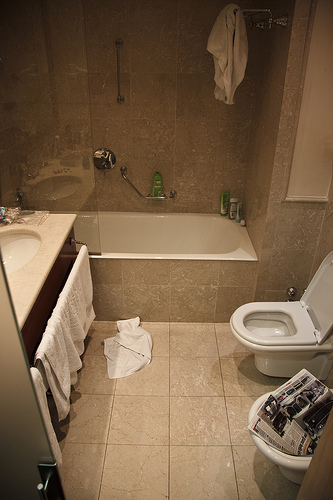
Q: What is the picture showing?
A: It is showing a bathroom.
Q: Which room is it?
A: It is a bathroom.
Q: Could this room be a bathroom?
A: Yes, it is a bathroom.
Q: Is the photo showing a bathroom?
A: Yes, it is showing a bathroom.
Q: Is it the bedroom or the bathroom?
A: It is the bathroom.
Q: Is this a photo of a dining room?
A: No, the picture is showing a bathroom.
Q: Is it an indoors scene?
A: Yes, it is indoors.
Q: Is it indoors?
A: Yes, it is indoors.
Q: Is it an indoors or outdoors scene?
A: It is indoors.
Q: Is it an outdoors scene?
A: No, it is indoors.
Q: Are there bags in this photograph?
A: Yes, there is a bag.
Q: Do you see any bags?
A: Yes, there is a bag.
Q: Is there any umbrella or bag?
A: Yes, there is a bag.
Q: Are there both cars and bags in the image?
A: No, there is a bag but no cars.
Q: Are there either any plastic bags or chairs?
A: Yes, there is a plastic bag.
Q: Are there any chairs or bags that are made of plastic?
A: Yes, the bag is made of plastic.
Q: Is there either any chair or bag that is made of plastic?
A: Yes, the bag is made of plastic.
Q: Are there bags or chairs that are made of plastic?
A: Yes, the bag is made of plastic.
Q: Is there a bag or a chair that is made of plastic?
A: Yes, the bag is made of plastic.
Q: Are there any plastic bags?
A: Yes, there is a bag that is made of plastic.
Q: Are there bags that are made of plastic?
A: Yes, there is a bag that is made of plastic.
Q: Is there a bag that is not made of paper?
A: Yes, there is a bag that is made of plastic.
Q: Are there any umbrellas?
A: No, there are no umbrellas.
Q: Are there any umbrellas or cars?
A: No, there are no umbrellas or cars.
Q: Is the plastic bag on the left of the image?
A: Yes, the bag is on the left of the image.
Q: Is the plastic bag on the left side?
A: Yes, the bag is on the left of the image.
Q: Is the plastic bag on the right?
A: No, the bag is on the left of the image.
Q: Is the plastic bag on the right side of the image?
A: No, the bag is on the left of the image.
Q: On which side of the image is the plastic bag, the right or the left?
A: The bag is on the left of the image.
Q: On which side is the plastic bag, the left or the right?
A: The bag is on the left of the image.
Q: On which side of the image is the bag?
A: The bag is on the left of the image.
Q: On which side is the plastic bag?
A: The bag is on the left of the image.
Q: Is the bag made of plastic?
A: Yes, the bag is made of plastic.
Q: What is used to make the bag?
A: The bag is made of plastic.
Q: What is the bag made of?
A: The bag is made of plastic.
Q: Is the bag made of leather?
A: No, the bag is made of plastic.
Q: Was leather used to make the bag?
A: No, the bag is made of plastic.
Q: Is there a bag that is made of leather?
A: No, there is a bag but it is made of plastic.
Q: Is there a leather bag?
A: No, there is a bag but it is made of plastic.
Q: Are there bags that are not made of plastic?
A: No, there is a bag but it is made of plastic.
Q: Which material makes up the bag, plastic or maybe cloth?
A: The bag is made of plastic.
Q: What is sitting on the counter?
A: The bag is sitting on the counter.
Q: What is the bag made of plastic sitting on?
A: The bag is sitting on the counter.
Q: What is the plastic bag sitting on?
A: The bag is sitting on the counter.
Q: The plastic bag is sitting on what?
A: The bag is sitting on the counter.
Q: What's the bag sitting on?
A: The bag is sitting on the counter.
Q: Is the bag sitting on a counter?
A: Yes, the bag is sitting on a counter.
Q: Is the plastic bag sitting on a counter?
A: Yes, the bag is sitting on a counter.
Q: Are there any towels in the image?
A: Yes, there is a towel.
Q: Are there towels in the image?
A: Yes, there is a towel.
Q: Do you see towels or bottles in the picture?
A: Yes, there is a towel.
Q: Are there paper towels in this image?
A: No, there are no paper towels.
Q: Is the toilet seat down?
A: Yes, the toilet seat is down.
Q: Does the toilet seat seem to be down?
A: Yes, the toilet seat is down.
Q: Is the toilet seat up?
A: No, the toilet seat is down.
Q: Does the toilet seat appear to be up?
A: No, the toilet seat is down.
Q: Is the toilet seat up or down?
A: The toilet seat is down.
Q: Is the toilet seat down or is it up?
A: The toilet seat is down.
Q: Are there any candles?
A: No, there are no candles.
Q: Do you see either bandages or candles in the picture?
A: No, there are no candles or bandages.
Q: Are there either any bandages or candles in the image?
A: No, there are no candles or bandages.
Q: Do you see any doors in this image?
A: Yes, there is a door.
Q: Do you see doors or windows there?
A: Yes, there is a door.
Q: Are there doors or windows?
A: Yes, there is a door.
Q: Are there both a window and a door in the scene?
A: No, there is a door but no windows.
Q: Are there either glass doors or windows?
A: Yes, there is a glass door.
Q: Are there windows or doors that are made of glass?
A: Yes, the door is made of glass.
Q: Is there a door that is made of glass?
A: Yes, there is a door that is made of glass.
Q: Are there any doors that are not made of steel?
A: Yes, there is a door that is made of glass.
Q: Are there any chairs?
A: No, there are no chairs.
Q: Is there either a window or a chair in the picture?
A: No, there are no chairs or windows.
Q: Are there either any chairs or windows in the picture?
A: No, there are no chairs or windows.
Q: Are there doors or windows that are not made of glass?
A: No, there is a door but it is made of glass.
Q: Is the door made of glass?
A: Yes, the door is made of glass.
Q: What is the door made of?
A: The door is made of glass.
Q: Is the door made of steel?
A: No, the door is made of glass.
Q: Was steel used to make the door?
A: No, the door is made of glass.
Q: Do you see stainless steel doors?
A: No, there is a door but it is made of glass.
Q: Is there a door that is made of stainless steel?
A: No, there is a door but it is made of glass.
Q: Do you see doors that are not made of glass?
A: No, there is a door but it is made of glass.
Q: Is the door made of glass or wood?
A: The door is made of glass.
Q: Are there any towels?
A: Yes, there is a towel.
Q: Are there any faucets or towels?
A: Yes, there is a towel.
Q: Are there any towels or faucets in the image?
A: Yes, there is a towel.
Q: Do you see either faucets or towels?
A: Yes, there is a towel.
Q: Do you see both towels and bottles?
A: Yes, there are both a towel and a bottle.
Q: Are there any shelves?
A: No, there are no shelves.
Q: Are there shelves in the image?
A: No, there are no shelves.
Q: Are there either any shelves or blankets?
A: No, there are no shelves or blankets.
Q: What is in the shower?
A: The towel is in the shower.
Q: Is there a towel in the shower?
A: Yes, there is a towel in the shower.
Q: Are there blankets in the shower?
A: No, there is a towel in the shower.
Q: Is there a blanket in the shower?
A: No, there is a towel in the shower.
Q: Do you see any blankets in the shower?
A: No, there is a towel in the shower.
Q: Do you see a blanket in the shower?
A: No, there is a towel in the shower.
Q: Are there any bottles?
A: Yes, there is a bottle.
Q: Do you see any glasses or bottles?
A: Yes, there is a bottle.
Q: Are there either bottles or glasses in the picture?
A: Yes, there is a bottle.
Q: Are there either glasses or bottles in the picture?
A: Yes, there is a bottle.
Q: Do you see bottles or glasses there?
A: Yes, there is a bottle.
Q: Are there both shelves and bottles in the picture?
A: No, there is a bottle but no shelves.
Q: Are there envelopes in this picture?
A: No, there are no envelopes.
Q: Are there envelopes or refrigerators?
A: No, there are no envelopes or refrigerators.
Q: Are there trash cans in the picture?
A: No, there are no trash cans.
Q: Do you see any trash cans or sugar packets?
A: No, there are no trash cans or sugar packets.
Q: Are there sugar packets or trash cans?
A: No, there are no trash cans or sugar packets.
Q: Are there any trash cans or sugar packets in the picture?
A: No, there are no trash cans or sugar packets.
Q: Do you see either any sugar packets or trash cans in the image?
A: No, there are no trash cans or sugar packets.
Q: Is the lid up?
A: Yes, the lid is up.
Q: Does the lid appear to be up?
A: Yes, the lid is up.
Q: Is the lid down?
A: No, the lid is up.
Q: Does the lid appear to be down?
A: No, the lid is up.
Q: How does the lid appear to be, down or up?
A: The lid is up.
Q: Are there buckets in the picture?
A: No, there are no buckets.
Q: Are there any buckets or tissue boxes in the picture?
A: No, there are no buckets or tissue boxes.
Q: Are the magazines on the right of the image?
A: Yes, the magazines are on the right of the image.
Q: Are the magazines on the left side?
A: No, the magazines are on the right of the image.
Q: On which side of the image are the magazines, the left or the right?
A: The magazines are on the right of the image.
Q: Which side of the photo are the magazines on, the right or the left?
A: The magazines are on the right of the image.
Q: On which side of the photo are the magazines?
A: The magazines are on the right of the image.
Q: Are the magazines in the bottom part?
A: Yes, the magazines are in the bottom of the image.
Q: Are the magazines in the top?
A: No, the magazines are in the bottom of the image.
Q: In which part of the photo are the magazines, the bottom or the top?
A: The magazines are in the bottom of the image.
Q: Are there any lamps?
A: No, there are no lamps.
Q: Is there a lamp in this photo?
A: No, there are no lamps.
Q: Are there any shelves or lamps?
A: No, there are no lamps or shelves.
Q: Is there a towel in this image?
A: Yes, there is a towel.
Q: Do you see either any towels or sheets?
A: Yes, there is a towel.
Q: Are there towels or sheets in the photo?
A: Yes, there is a towel.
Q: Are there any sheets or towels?
A: Yes, there is a towel.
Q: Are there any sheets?
A: No, there are no sheets.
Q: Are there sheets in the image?
A: No, there are no sheets.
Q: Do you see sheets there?
A: No, there are no sheets.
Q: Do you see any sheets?
A: No, there are no sheets.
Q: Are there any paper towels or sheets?
A: No, there are no sheets or paper towels.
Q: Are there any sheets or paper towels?
A: No, there are no sheets or paper towels.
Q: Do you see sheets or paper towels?
A: No, there are no sheets or paper towels.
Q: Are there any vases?
A: No, there are no vases.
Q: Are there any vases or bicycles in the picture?
A: No, there are no vases or bicycles.